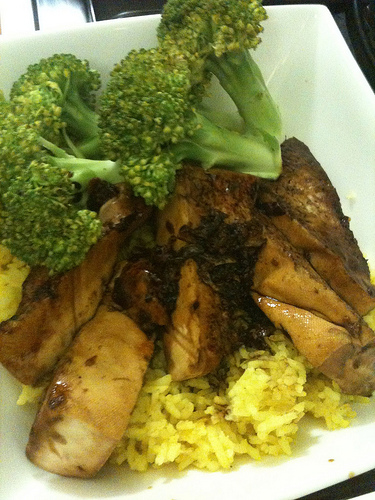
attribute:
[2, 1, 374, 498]
plate — white, square, glass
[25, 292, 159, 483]
chicken — glistening, grilled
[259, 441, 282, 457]
rice — yellow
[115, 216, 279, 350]
sauce — black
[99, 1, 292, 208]
broccoli — steamed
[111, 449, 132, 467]
rice — fried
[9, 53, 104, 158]
broccoli — green